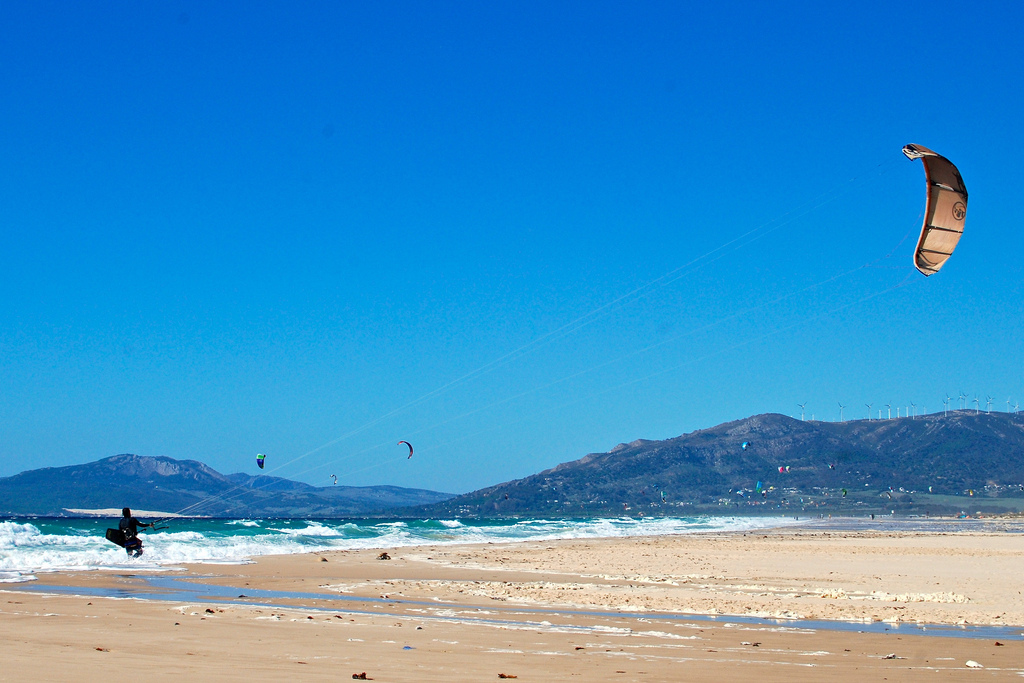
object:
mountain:
[132, 455, 280, 518]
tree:
[402, 471, 547, 520]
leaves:
[252, 480, 320, 520]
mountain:
[430, 410, 1022, 511]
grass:
[671, 414, 885, 520]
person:
[104, 508, 164, 562]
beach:
[0, 504, 1022, 681]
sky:
[83, 74, 850, 523]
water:
[0, 510, 573, 556]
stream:
[624, 610, 971, 638]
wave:
[0, 517, 76, 580]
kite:
[898, 141, 967, 278]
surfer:
[106, 508, 156, 562]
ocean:
[0, 515, 194, 578]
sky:
[135, 55, 593, 271]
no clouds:
[580, 41, 860, 262]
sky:
[36, 35, 340, 315]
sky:
[68, 134, 295, 270]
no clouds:
[444, 42, 880, 279]